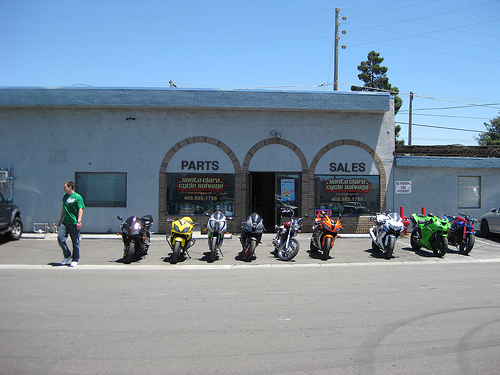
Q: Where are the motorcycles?
A: By the building.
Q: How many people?
A: One.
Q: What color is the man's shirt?
A: Green.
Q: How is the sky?
A: Clear.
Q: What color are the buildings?
A: White.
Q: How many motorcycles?
A: Nine.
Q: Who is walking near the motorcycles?
A: The man.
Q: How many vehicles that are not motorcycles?
A: Two.